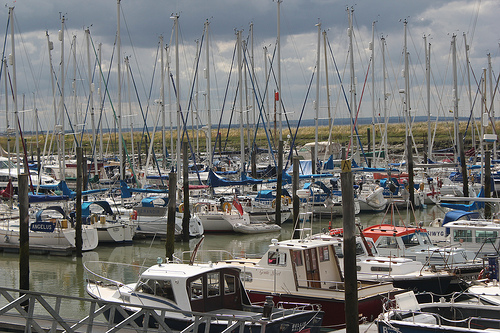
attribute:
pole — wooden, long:
[75, 146, 84, 256]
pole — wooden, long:
[16, 172, 32, 312]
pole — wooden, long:
[166, 170, 177, 257]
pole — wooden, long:
[182, 140, 191, 243]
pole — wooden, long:
[275, 139, 284, 223]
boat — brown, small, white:
[78, 255, 323, 332]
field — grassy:
[2, 119, 499, 150]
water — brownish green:
[4, 197, 473, 323]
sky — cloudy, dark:
[2, 0, 499, 136]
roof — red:
[365, 224, 426, 237]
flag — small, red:
[275, 89, 280, 104]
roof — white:
[139, 259, 236, 284]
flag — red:
[232, 198, 243, 216]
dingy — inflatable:
[231, 219, 283, 236]